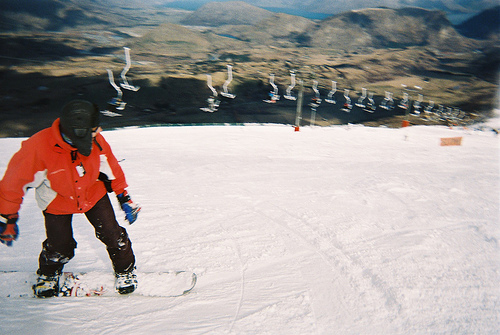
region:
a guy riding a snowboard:
[14, 103, 182, 315]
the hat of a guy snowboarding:
[60, 101, 101, 152]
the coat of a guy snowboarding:
[0, 138, 135, 219]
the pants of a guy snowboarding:
[40, 211, 142, 268]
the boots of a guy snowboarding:
[28, 265, 136, 300]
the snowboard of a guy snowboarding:
[14, 259, 198, 310]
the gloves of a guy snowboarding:
[0, 212, 34, 249]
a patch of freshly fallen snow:
[190, 178, 332, 260]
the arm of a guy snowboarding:
[5, 139, 36, 230]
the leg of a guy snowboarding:
[30, 201, 67, 275]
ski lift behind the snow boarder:
[100, 26, 467, 143]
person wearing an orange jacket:
[16, 128, 141, 203]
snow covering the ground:
[233, 193, 398, 303]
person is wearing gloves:
[118, 201, 140, 222]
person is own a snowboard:
[6, 261, 209, 307]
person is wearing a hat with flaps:
[56, 98, 103, 155]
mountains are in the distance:
[85, 11, 410, 63]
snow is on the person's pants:
[41, 242, 68, 273]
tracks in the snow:
[298, 195, 396, 329]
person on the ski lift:
[264, 75, 284, 102]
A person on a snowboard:
[2, 97, 204, 309]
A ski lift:
[15, 22, 485, 133]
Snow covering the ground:
[0, 115, 498, 332]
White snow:
[1, 126, 497, 333]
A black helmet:
[55, 97, 105, 158]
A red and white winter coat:
[1, 125, 123, 212]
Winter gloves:
[4, 194, 141, 237]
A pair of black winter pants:
[36, 199, 137, 284]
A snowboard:
[1, 269, 201, 307]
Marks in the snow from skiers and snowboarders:
[201, 170, 413, 332]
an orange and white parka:
[1, 118, 123, 218]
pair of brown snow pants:
[43, 197, 112, 272]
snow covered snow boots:
[31, 238, 136, 296]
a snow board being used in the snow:
[2, 266, 198, 304]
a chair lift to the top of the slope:
[83, 38, 482, 118]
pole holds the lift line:
[293, 81, 307, 135]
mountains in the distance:
[0, 3, 499, 112]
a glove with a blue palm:
[116, 194, 143, 224]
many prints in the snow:
[2, 127, 490, 332]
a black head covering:
[53, 95, 102, 155]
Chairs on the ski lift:
[101, 44, 469, 125]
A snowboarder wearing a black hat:
[1, 96, 199, 300]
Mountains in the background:
[0, 0, 499, 139]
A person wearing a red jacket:
[0, 98, 144, 299]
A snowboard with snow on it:
[0, 271, 197, 299]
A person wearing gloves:
[1, 95, 139, 298]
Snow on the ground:
[0, 123, 498, 333]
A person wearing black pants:
[1, 99, 141, 301]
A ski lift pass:
[75, 161, 88, 178]